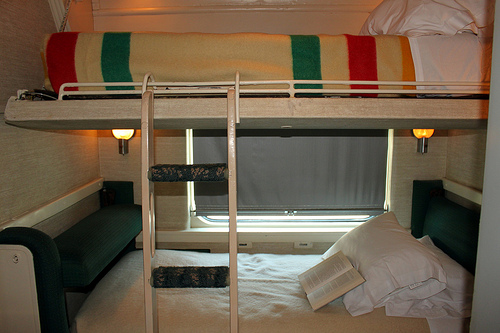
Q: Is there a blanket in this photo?
A: Yes, there is a blanket.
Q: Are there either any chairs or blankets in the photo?
A: Yes, there is a blanket.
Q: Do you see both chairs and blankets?
A: No, there is a blanket but no chairs.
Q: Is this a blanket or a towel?
A: This is a blanket.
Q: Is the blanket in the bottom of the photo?
A: No, the blanket is in the top of the image.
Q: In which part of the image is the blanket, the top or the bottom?
A: The blanket is in the top of the image.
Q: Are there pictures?
A: No, there are no pictures.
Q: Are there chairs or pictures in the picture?
A: No, there are no pictures or chairs.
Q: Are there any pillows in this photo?
A: Yes, there is a pillow.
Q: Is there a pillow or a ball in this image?
A: Yes, there is a pillow.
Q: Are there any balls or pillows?
A: Yes, there is a pillow.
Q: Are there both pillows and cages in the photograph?
A: No, there is a pillow but no cages.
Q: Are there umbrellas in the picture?
A: No, there are no umbrellas.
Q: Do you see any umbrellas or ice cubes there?
A: No, there are no umbrellas or ice cubes.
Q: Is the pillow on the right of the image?
A: Yes, the pillow is on the right of the image.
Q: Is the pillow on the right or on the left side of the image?
A: The pillow is on the right of the image.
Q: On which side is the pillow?
A: The pillow is on the right of the image.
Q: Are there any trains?
A: Yes, there is a train.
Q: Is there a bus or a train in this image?
A: Yes, there is a train.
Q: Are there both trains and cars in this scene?
A: No, there is a train but no cars.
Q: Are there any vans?
A: No, there are no vans.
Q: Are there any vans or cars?
A: No, there are no vans or cars.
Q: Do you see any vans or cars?
A: No, there are no vans or cars.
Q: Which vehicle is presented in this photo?
A: The vehicle is a train.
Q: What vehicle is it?
A: The vehicle is a train.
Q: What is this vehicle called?
A: This is a train.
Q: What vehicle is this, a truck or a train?
A: This is a train.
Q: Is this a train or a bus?
A: This is a train.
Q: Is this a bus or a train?
A: This is a train.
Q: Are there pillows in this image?
A: Yes, there is a pillow.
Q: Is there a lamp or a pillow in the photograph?
A: Yes, there is a pillow.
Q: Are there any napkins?
A: No, there are no napkins.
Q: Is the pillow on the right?
A: Yes, the pillow is on the right of the image.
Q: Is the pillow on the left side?
A: No, the pillow is on the right of the image.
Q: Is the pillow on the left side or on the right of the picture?
A: The pillow is on the right of the image.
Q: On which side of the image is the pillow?
A: The pillow is on the right of the image.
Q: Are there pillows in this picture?
A: Yes, there is a pillow.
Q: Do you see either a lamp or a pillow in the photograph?
A: Yes, there is a pillow.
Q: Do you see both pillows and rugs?
A: No, there is a pillow but no rugs.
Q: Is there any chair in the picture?
A: No, there are no chairs.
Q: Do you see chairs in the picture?
A: No, there are no chairs.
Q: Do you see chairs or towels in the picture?
A: No, there are no chairs or towels.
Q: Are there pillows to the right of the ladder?
A: Yes, there is a pillow to the right of the ladder.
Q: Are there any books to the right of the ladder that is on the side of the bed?
A: No, there is a pillow to the right of the ladder.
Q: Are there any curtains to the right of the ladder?
A: Yes, there is a curtain to the right of the ladder.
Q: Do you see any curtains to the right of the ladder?
A: Yes, there is a curtain to the right of the ladder.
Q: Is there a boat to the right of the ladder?
A: No, there is a curtain to the right of the ladder.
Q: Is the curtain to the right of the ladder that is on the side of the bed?
A: Yes, the curtain is to the right of the ladder.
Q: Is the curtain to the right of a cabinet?
A: No, the curtain is to the right of the ladder.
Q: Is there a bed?
A: Yes, there is a bed.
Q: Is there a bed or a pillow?
A: Yes, there is a bed.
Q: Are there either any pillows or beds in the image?
A: Yes, there is a bed.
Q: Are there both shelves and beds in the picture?
A: No, there is a bed but no shelves.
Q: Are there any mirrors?
A: No, there are no mirrors.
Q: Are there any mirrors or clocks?
A: No, there are no mirrors or clocks.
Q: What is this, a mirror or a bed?
A: This is a bed.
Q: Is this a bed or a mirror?
A: This is a bed.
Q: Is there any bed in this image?
A: Yes, there is a bed.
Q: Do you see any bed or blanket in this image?
A: Yes, there is a bed.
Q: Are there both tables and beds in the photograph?
A: No, there is a bed but no tables.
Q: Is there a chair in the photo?
A: No, there are no chairs.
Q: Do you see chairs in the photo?
A: No, there are no chairs.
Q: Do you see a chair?
A: No, there are no chairs.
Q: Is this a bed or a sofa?
A: This is a bed.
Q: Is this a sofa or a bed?
A: This is a bed.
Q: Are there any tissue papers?
A: No, there are no tissue papers.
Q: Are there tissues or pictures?
A: No, there are no tissues or pictures.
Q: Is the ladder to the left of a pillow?
A: Yes, the ladder is to the left of a pillow.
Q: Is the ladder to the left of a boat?
A: No, the ladder is to the left of a pillow.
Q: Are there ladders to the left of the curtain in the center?
A: Yes, there is a ladder to the left of the curtain.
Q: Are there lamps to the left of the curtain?
A: No, there is a ladder to the left of the curtain.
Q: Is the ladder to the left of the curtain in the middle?
A: Yes, the ladder is to the left of the curtain.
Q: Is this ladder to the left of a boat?
A: No, the ladder is to the left of the curtain.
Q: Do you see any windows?
A: Yes, there is a window.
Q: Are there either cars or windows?
A: Yes, there is a window.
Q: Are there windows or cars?
A: Yes, there is a window.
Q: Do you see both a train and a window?
A: Yes, there are both a window and a train.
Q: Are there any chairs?
A: No, there are no chairs.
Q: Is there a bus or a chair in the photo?
A: No, there are no chairs or buses.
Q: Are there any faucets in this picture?
A: No, there are no faucets.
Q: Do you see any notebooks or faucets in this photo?
A: No, there are no faucets or notebooks.